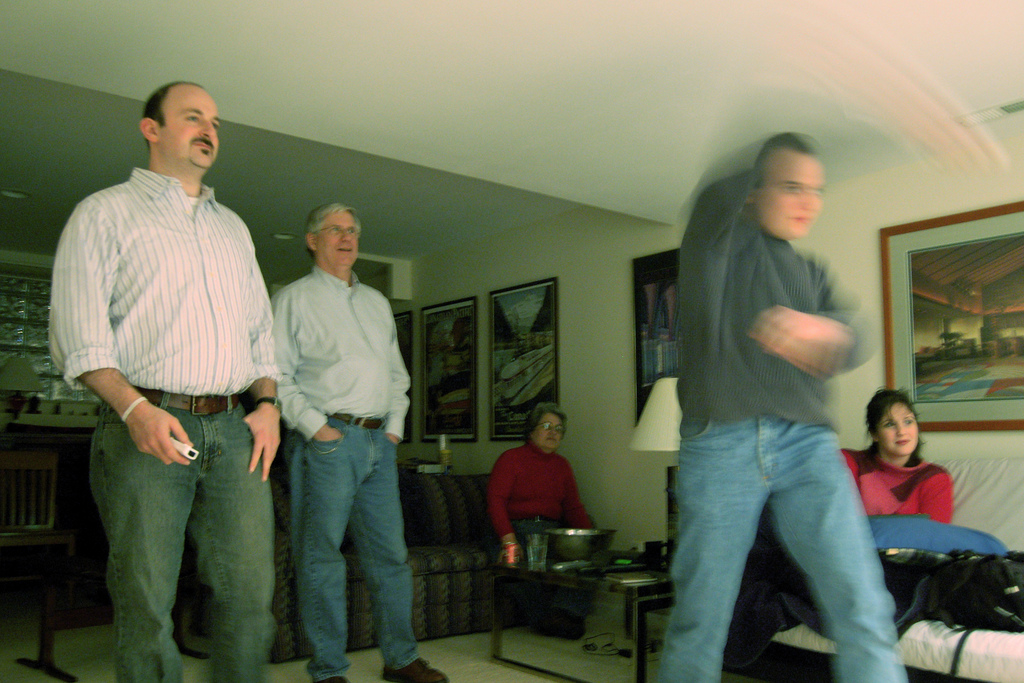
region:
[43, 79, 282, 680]
man holding a white wii controller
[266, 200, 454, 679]
man with hands in pockets wearing blue jeans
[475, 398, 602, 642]
older woman in red sweater sitting on couch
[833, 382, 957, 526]
younger woman wearing red sweater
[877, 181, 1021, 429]
large wood picture frame hanging on wall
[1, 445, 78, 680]
dark brown wood bar chair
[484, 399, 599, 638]
woman wearing corrective glasses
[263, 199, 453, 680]
older man wearing glasses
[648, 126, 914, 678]
man standing and swinging his arm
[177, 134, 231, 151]
mustache on the man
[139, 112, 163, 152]
right ear on man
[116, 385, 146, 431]
white band on wrist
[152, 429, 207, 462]
white remote in hand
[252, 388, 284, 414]
watch on man's wrist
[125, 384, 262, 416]
belt on waist of man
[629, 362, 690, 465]
white lampshade in room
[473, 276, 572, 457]
picture on the wall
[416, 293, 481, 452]
picture in the wall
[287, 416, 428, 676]
blue jeans on man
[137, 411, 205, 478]
a man holding a white game controller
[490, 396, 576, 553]
a woman sitting on a couch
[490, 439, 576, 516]
a woman wearing a red shirt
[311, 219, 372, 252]
a man wearing eye glasses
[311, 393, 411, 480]
a man with his hands in his pockets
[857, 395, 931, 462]
a woman with brown hair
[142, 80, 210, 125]
a man with short hair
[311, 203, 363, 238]
a man with white hair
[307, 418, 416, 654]
a man wearing blue jeans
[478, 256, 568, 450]
a picture hanging on the wall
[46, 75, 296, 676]
man holding wii remote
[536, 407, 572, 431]
glasses on her face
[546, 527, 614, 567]
a silver bowl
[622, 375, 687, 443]
a white lamp shade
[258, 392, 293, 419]
a black watch on wrist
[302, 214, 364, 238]
glasses on his face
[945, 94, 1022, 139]
air vent in ceiling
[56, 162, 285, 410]
a stripped button down shirt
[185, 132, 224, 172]
a goatee on the man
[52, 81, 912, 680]
the men are standing up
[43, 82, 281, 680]
the man holding the wii controller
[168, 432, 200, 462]
the wii controller is white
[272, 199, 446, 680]
the man wearing blue jeans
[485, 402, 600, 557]
the woman is sitting down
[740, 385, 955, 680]
the woman is sitting down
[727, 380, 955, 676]
the woman has dark hair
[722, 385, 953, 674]
the woman is wearing a red long sleeved top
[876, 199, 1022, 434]
the large framed picture is hanging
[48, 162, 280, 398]
the buttoned up shirt has thin stripes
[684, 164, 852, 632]
a person wearing a shirt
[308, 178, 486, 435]
a person wearing a shirt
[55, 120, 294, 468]
a person wearing a shirt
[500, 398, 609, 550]
a person wearin ga shirt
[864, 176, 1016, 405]
a picture on the wall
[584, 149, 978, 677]
a person standing inside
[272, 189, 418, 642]
a person standing inside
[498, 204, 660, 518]
a picture on the wall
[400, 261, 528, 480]
a picture on the wall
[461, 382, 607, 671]
a woman is sitting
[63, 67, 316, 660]
a person is playing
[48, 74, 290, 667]
a person is standing up